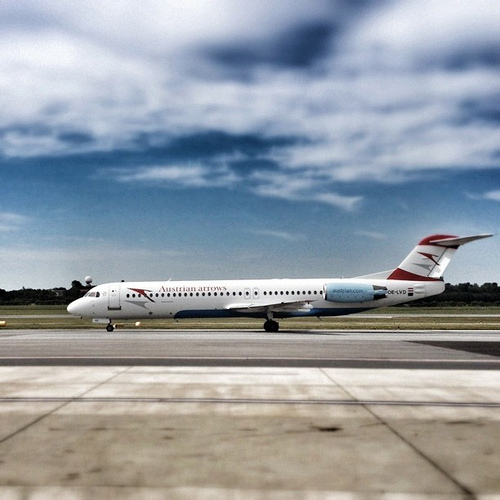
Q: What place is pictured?
A: It is an airport.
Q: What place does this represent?
A: It represents the airport.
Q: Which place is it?
A: It is an airport.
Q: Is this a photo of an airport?
A: Yes, it is showing an airport.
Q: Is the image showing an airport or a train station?
A: It is showing an airport.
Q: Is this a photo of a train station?
A: No, the picture is showing an airport.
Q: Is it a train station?
A: No, it is an airport.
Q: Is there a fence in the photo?
A: No, there are no fences.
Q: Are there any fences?
A: No, there are no fences.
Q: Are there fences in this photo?
A: No, there are no fences.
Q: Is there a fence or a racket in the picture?
A: No, there are no fences or rackets.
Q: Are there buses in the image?
A: No, there are no buses.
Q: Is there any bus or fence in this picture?
A: No, there are no buses or fences.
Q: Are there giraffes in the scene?
A: No, there are no giraffes.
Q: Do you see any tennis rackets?
A: No, there are no tennis rackets.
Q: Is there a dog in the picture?
A: No, there are no dogs.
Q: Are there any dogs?
A: No, there are no dogs.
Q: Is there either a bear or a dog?
A: No, there are no dogs or bears.